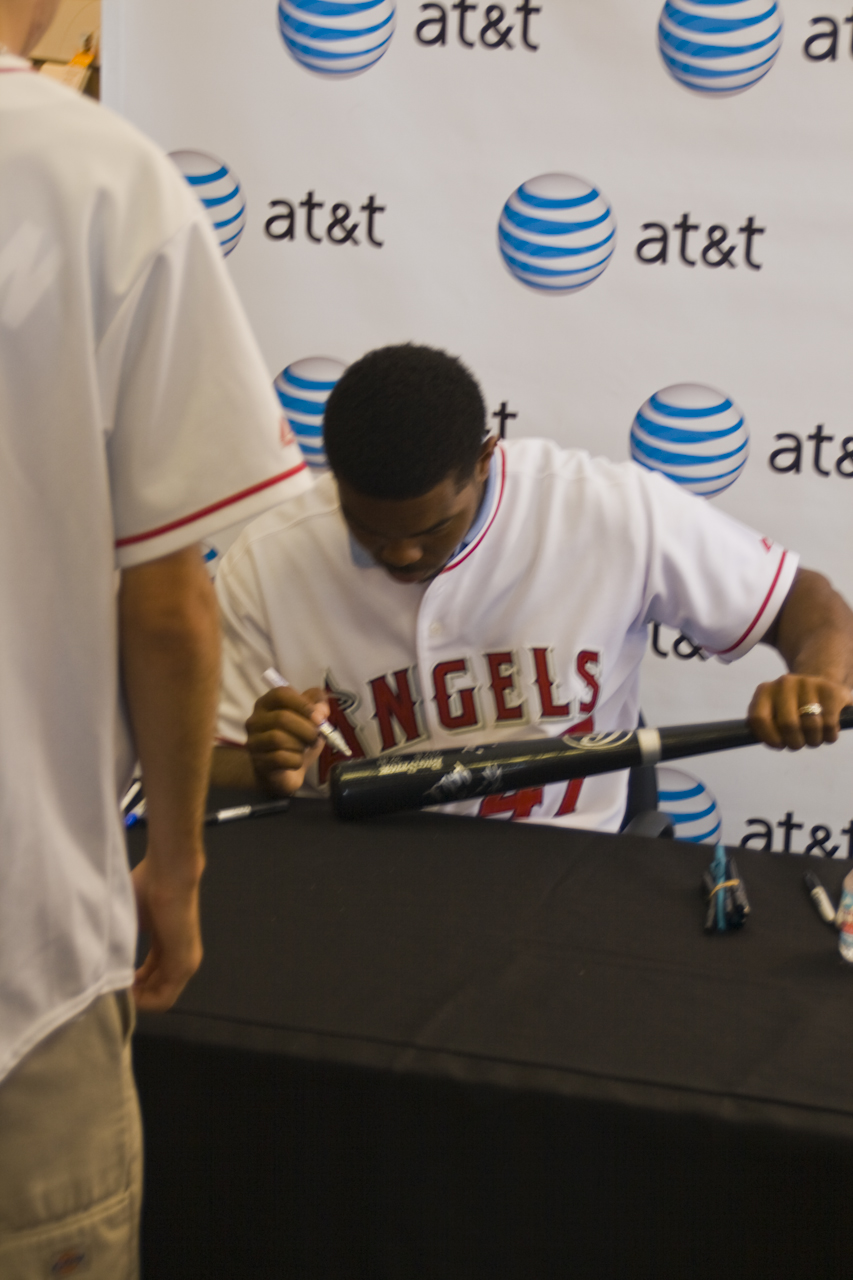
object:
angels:
[318, 648, 598, 788]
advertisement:
[496, 173, 764, 295]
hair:
[323, 341, 491, 502]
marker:
[203, 798, 290, 826]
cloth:
[123, 809, 851, 1112]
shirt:
[0, 47, 315, 1095]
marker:
[259, 666, 353, 757]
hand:
[245, 685, 332, 795]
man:
[209, 339, 853, 835]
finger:
[799, 675, 824, 746]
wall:
[98, 0, 853, 863]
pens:
[702, 845, 751, 936]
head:
[322, 343, 497, 583]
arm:
[639, 465, 853, 674]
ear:
[475, 435, 501, 482]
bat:
[329, 703, 853, 823]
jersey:
[213, 437, 802, 835]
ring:
[799, 701, 823, 715]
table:
[123, 803, 853, 1280]